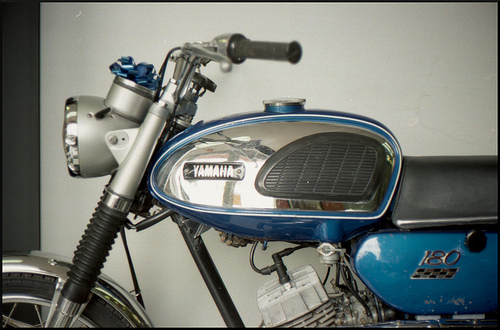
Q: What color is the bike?
A: Blue and Silver.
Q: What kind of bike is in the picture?
A: A motorcycle.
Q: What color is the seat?
A: Black.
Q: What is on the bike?
A: A seat.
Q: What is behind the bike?
A: A wall.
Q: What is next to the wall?
A: A motorcycle.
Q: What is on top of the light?
A: A bow.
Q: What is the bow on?
A: The light.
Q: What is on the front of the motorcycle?
A: A light.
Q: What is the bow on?
A: A motorcycle.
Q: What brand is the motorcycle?
A: Yamaha.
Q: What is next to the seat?
A: A tank.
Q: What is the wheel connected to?
A: The handlebars.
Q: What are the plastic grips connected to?
A: Chrome handlebars.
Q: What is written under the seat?
A: A decal.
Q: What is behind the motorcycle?
A: A wall.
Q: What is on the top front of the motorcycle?
A: A light.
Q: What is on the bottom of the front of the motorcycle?
A: A wheel.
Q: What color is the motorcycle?
A: Blue.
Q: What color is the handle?
A: Black.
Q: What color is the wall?
A: White.